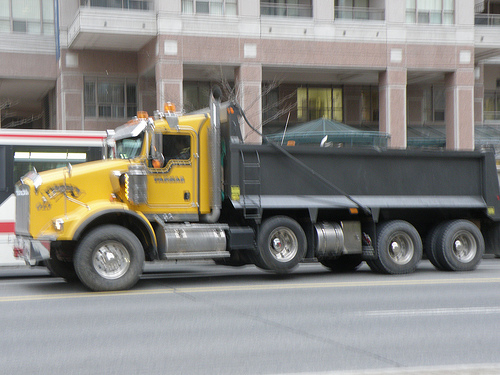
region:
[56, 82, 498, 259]
yellow and black truck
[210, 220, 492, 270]
black wheels on truck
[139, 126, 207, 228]
yellow door on truck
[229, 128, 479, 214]
black bed on truck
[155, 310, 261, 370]
road is light grey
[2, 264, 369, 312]
yellow line on road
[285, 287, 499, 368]
white line on road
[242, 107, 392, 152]
green tent behind truck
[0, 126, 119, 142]
red stripe on building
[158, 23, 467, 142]
brown pillars on building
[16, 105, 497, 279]
a yellow and black dump truck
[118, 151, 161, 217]
the silver air filter on the truck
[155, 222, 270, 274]
the fuel tank on the dump truck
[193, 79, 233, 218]
the chrome stack on the truck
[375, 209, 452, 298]
the double tires on the truck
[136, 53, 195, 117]
brown and white square columns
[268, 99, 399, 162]
green umbrellas over tables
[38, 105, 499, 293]
the truck is parked next to the curb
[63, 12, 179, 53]
the balcony on the second floor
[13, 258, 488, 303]
double yellow line along the street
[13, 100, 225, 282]
The truck cab is yellow.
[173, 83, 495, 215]
The truck has a black dump bed.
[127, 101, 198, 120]
The truck cab has orange lights.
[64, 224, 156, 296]
The truck has a tire.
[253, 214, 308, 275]
The truck has a tire.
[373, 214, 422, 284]
The truck has a tire.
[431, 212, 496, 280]
The truck has a tire.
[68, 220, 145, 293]
The tire is rubber.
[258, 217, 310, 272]
The tire is rubber.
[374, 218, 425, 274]
The tire is rubber.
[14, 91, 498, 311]
truck in the road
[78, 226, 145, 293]
front wheel of a truck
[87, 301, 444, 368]
street where truck is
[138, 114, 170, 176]
side view mirror on truck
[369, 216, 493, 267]
back tires on a truck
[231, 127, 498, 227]
dump area of a truck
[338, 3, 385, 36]
window of a building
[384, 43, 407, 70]
decoration on a building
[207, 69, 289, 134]
bare branches of a tree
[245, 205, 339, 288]
Wheel of a truck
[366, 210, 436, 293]
Wheel of a truck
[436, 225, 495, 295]
Wheel of a truck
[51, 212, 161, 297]
Wheel of a truck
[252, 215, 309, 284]
Wheel of a truck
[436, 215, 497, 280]
Wheel of a truck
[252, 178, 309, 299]
Wheel of a truck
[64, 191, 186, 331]
Wheel of a truck